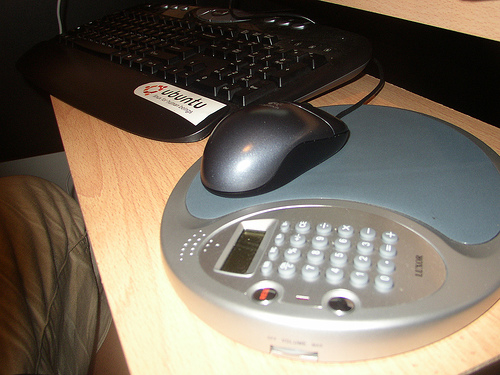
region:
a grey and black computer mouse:
[192, 91, 349, 205]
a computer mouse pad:
[157, 87, 498, 365]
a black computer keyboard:
[10, 9, 368, 138]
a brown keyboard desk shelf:
[49, 27, 498, 373]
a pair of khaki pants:
[5, 169, 110, 374]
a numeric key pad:
[266, 210, 398, 294]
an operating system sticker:
[128, 73, 224, 128]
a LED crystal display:
[216, 222, 267, 278]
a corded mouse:
[195, 49, 409, 197]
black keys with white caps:
[203, 37, 320, 107]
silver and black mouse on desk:
[192, 96, 357, 193]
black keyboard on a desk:
[42, 2, 374, 112]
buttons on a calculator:
[262, 212, 408, 302]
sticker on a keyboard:
[127, 70, 224, 135]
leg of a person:
[0, 164, 131, 374]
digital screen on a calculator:
[214, 218, 274, 283]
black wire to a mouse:
[338, 78, 389, 123]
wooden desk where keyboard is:
[86, 144, 148, 229]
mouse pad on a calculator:
[360, 125, 457, 192]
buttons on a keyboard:
[222, 40, 304, 87]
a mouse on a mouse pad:
[127, 14, 469, 269]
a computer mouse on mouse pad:
[160, 50, 394, 254]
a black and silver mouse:
[155, 50, 465, 232]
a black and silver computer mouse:
[160, 70, 354, 191]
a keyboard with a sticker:
[22, 0, 429, 184]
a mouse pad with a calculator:
[154, 78, 495, 346]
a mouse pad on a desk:
[162, 21, 464, 267]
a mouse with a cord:
[196, 12, 447, 181]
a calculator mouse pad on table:
[111, 72, 458, 363]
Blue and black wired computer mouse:
[195, 88, 348, 185]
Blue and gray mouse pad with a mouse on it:
[180, 111, 490, 251]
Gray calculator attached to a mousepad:
[163, 170, 435, 325]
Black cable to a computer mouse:
[339, 69, 396, 125]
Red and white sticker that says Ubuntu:
[124, 75, 226, 130]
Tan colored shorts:
[0, 191, 109, 363]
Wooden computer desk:
[85, 134, 173, 331]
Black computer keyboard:
[54, 0, 291, 87]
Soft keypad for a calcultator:
[270, 217, 414, 302]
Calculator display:
[223, 222, 270, 296]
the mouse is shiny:
[185, 77, 422, 258]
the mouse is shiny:
[180, 50, 315, 250]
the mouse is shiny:
[195, 100, 337, 216]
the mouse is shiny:
[217, 104, 297, 235]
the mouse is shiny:
[245, 92, 387, 329]